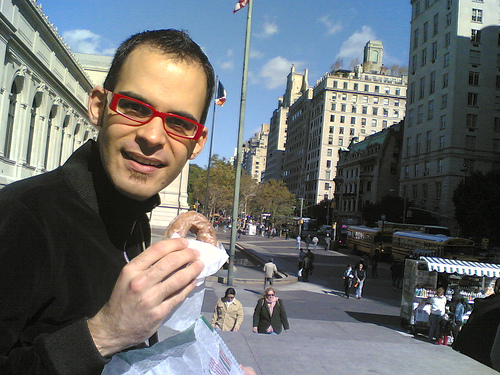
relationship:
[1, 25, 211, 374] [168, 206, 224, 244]
man eats donut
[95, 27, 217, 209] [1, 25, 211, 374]
head of man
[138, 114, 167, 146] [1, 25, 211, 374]
nose of man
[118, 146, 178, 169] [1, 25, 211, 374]
mouth of man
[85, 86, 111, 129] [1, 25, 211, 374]
ear of man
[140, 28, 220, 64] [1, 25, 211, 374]
hair of man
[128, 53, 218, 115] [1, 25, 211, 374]
forehead of man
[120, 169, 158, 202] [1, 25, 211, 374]
beard of man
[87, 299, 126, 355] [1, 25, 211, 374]
wrist of man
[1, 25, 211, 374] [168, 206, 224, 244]
man holds donut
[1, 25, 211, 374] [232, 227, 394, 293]
man in front of street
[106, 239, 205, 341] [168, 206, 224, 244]
hand holds donut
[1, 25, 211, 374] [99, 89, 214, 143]
man wears glasses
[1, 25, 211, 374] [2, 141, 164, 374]
man wearing jacket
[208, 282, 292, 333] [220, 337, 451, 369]
two women walk up stairs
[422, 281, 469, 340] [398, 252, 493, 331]
two people stand at food truck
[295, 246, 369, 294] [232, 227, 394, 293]
people are on street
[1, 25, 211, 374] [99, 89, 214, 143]
man wearing glasses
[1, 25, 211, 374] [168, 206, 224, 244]
man holding donut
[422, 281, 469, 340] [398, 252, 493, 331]
two people order from food truck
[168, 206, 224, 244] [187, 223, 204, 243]
donut has hole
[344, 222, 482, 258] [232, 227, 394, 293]
two buses are on street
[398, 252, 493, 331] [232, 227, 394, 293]
food truck on side of street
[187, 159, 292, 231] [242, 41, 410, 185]
trees between buildings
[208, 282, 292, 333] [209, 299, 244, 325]
two women wearing coat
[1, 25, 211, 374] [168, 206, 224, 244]
man has donut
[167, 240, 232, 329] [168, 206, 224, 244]
napkin around donut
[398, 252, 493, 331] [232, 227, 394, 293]
food truck by street